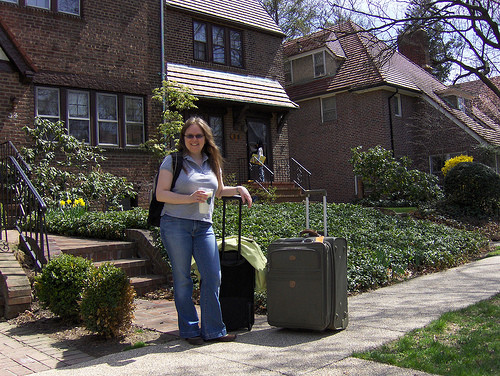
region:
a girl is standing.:
[153, 115, 254, 346]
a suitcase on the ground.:
[265, 187, 348, 331]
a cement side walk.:
[2, 252, 497, 374]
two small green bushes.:
[28, 250, 136, 342]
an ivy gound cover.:
[21, 201, 496, 315]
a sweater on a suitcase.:
[188, 195, 266, 332]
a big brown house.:
[281, 21, 498, 204]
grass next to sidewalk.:
[350, 288, 499, 373]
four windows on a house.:
[33, 84, 150, 148]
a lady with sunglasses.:
[153, 114, 253, 346]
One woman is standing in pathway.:
[163, 124, 236, 336]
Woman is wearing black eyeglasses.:
[180, 124, 223, 156]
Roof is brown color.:
[208, 1, 465, 103]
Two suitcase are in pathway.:
[193, 174, 348, 336]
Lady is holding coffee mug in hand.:
[192, 186, 222, 226]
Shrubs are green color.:
[339, 203, 427, 249]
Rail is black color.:
[4, 149, 51, 248]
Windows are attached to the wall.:
[20, 86, 182, 155]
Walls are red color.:
[221, 98, 416, 162]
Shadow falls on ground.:
[53, 191, 483, 341]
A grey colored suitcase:
[265, 240, 351, 330]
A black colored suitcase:
[215, 196, 258, 328]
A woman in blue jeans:
[148, 117, 250, 341]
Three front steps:
[64, 244, 166, 294]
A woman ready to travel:
[148, 120, 357, 342]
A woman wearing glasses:
[174, 118, 221, 168]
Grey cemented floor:
[130, 322, 301, 374]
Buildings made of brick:
[0, 2, 403, 205]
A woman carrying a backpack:
[149, 119, 237, 346]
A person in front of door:
[247, 121, 277, 191]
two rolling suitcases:
[211, 187, 348, 332]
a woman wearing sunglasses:
[148, 115, 252, 342]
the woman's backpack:
[147, 152, 184, 227]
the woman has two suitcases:
[148, 115, 349, 342]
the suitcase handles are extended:
[218, 186, 328, 253]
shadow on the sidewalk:
[51, 328, 213, 368]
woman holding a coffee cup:
[148, 117, 252, 346]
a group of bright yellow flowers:
[56, 196, 90, 220]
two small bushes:
[33, 252, 136, 344]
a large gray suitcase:
[266, 187, 350, 332]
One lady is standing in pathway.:
[151, 112, 237, 337]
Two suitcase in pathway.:
[216, 178, 338, 342]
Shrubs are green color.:
[351, 216, 431, 293]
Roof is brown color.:
[305, 29, 437, 89]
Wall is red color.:
[306, 124, 409, 161]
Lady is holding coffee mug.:
[184, 181, 223, 235]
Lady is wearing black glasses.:
[179, 127, 212, 149]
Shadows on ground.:
[4, 218, 438, 374]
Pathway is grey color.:
[368, 286, 451, 326]